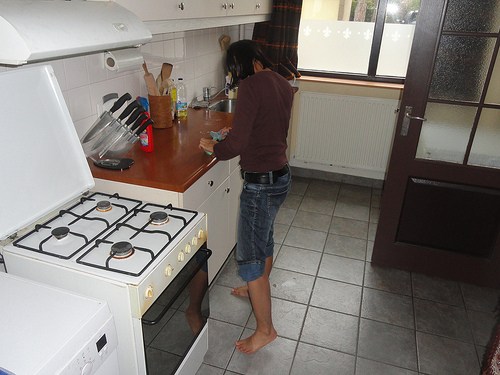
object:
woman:
[198, 38, 296, 354]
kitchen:
[0, 0, 500, 375]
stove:
[9, 191, 198, 277]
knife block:
[80, 109, 140, 166]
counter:
[85, 86, 298, 194]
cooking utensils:
[142, 62, 176, 96]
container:
[148, 94, 173, 129]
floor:
[192, 174, 499, 374]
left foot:
[234, 329, 278, 355]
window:
[296, 0, 421, 79]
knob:
[144, 285, 153, 299]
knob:
[164, 263, 174, 277]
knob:
[177, 251, 185, 262]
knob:
[185, 242, 192, 254]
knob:
[192, 237, 199, 246]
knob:
[197, 230, 204, 240]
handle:
[400, 106, 427, 138]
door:
[370, 0, 500, 291]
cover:
[0, 63, 95, 240]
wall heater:
[293, 90, 400, 174]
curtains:
[250, 0, 302, 82]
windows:
[414, 1, 499, 174]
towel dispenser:
[106, 57, 115, 69]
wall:
[70, 61, 105, 87]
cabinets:
[112, 0, 272, 36]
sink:
[208, 100, 236, 114]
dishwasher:
[0, 271, 122, 374]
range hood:
[0, 0, 152, 68]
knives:
[80, 92, 156, 159]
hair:
[226, 39, 275, 91]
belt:
[239, 165, 289, 185]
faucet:
[203, 86, 232, 103]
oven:
[0, 64, 208, 375]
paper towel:
[103, 52, 144, 75]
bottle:
[176, 77, 188, 120]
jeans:
[234, 162, 293, 283]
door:
[141, 241, 213, 375]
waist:
[242, 143, 284, 166]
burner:
[149, 211, 169, 223]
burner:
[111, 240, 133, 256]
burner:
[97, 200, 111, 210]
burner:
[51, 226, 71, 239]